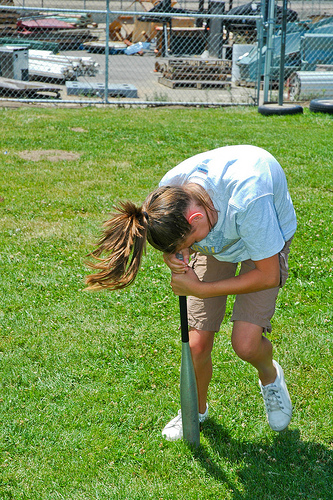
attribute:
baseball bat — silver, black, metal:
[158, 295, 218, 444]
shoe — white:
[256, 369, 296, 431]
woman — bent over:
[126, 145, 312, 461]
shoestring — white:
[266, 388, 286, 411]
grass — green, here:
[134, 129, 189, 146]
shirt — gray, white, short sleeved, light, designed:
[157, 151, 296, 244]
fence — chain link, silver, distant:
[197, 26, 224, 40]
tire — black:
[307, 79, 332, 116]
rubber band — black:
[131, 201, 176, 235]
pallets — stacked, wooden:
[168, 53, 236, 89]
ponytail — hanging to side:
[106, 221, 127, 298]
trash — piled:
[226, 4, 327, 98]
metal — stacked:
[38, 47, 102, 79]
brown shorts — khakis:
[201, 302, 292, 327]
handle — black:
[168, 301, 195, 348]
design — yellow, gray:
[191, 232, 242, 259]